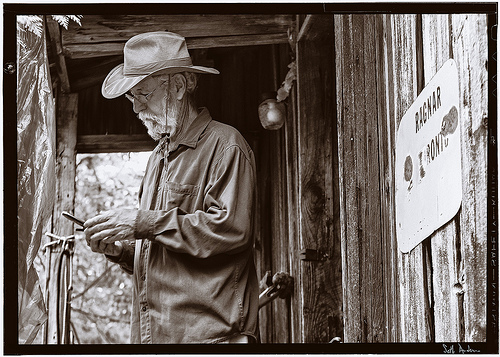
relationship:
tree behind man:
[80, 161, 127, 216] [90, 55, 310, 344]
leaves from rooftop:
[20, 18, 81, 32] [45, 100, 275, 174]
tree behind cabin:
[80, 161, 127, 216] [245, 87, 475, 351]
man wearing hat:
[95, 37, 254, 347] [97, 29, 210, 88]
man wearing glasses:
[95, 37, 254, 347] [124, 87, 166, 100]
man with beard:
[95, 37, 254, 347] [139, 107, 178, 136]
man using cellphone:
[95, 37, 254, 347] [63, 212, 89, 223]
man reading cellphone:
[95, 37, 254, 347] [63, 212, 89, 223]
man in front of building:
[95, 37, 254, 347] [237, 16, 499, 315]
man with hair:
[95, 37, 254, 347] [177, 72, 199, 90]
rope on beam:
[37, 234, 79, 347] [58, 94, 75, 315]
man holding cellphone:
[95, 37, 254, 347] [63, 212, 89, 223]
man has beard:
[95, 37, 254, 347] [139, 107, 178, 136]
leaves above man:
[20, 18, 81, 32] [95, 37, 254, 347]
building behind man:
[237, 16, 499, 315] [95, 37, 254, 347]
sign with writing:
[369, 63, 465, 223] [408, 106, 448, 119]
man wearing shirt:
[95, 37, 254, 347] [129, 112, 266, 340]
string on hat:
[163, 78, 173, 173] [97, 29, 210, 88]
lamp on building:
[256, 90, 285, 129] [237, 16, 499, 315]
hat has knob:
[97, 29, 210, 88] [160, 132, 168, 136]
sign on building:
[369, 63, 465, 223] [237, 16, 499, 315]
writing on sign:
[408, 106, 448, 119] [369, 63, 465, 223]